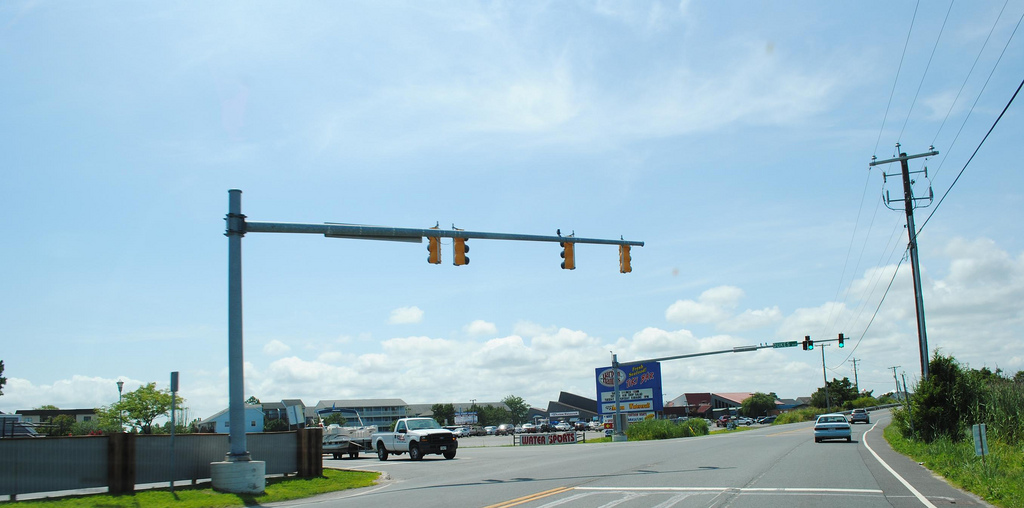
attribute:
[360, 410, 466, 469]
truck — white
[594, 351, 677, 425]
wall — blue, advertising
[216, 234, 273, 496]
pole — gray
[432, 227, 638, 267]
signal — street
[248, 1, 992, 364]
wires — electrical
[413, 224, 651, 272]
lights — yellow, traffic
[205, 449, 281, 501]
pole — base, cement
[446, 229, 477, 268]
signal — street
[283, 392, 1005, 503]
street — black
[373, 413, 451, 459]
truck — white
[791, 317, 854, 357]
traffic lights — green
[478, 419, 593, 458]
rectangular sign —  red and white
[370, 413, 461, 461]
truck — white, stopped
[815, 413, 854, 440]
car — white , Small , driving 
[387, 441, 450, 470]
truck — white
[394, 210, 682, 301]
traffic lights — yellow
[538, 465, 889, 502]
line — white, painted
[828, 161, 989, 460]
pole — utility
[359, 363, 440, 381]
clouds — white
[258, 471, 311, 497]
grass — green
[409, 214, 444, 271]
traffic light — hanging, metal, yellow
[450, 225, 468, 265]
traffic light — yellow, hanging, metal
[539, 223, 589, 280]
traffic light — metal, hanging, yellow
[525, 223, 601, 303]
traffic light — yellow, hanging, metal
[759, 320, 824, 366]
light — bright, green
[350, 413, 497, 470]
truck — white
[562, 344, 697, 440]
sign — large, blue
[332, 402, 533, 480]
truck — white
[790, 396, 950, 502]
car — white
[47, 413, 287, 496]
fence — light brown